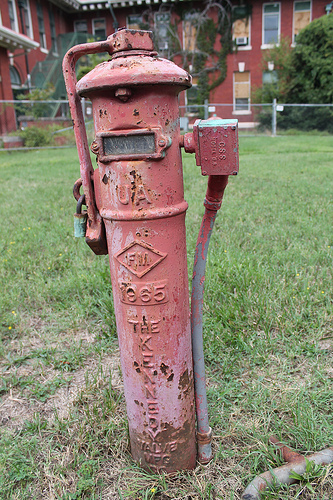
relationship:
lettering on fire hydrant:
[111, 182, 178, 471] [60, 25, 240, 472]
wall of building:
[280, 0, 292, 46] [1, 0, 331, 146]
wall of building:
[171, 0, 333, 121] [1, 0, 331, 146]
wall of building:
[30, 0, 40, 40] [1, 0, 331, 146]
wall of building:
[107, 9, 126, 35] [1, 0, 331, 146]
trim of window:
[259, 1, 280, 49] [251, 7, 292, 66]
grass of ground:
[2, 137, 332, 499] [2, 135, 332, 498]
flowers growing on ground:
[7, 196, 65, 326] [271, 190, 304, 224]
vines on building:
[205, 65, 227, 91] [2, 3, 326, 98]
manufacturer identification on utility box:
[123, 314, 183, 471] [59, 23, 242, 475]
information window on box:
[102, 131, 155, 158] [94, 128, 160, 161]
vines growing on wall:
[182, 41, 236, 99] [166, 32, 312, 130]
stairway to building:
[16, 30, 92, 117] [3, 1, 326, 112]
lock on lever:
[56, 185, 94, 239] [53, 35, 107, 215]